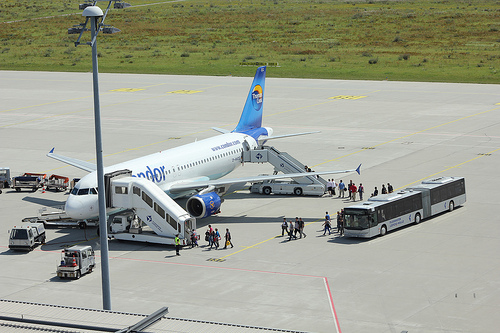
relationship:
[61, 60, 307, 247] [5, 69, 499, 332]
plane on runway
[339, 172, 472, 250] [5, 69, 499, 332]
bus on runway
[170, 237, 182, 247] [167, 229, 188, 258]
vest on director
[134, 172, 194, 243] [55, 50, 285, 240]
stairs on plane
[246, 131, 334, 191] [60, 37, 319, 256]
stairs on plane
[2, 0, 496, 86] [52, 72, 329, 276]
grass behind plane